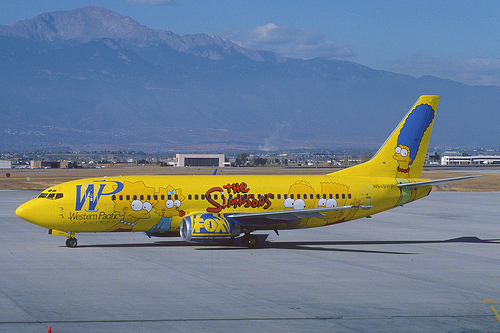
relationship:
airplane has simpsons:
[14, 92, 476, 247] [113, 103, 433, 233]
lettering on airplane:
[204, 182, 273, 213] [14, 92, 476, 247]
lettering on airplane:
[73, 176, 121, 211] [14, 92, 476, 247]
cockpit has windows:
[35, 190, 64, 210] [38, 190, 63, 200]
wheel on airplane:
[65, 234, 77, 245] [14, 96, 476, 246]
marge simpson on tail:
[391, 104, 435, 206] [382, 94, 477, 212]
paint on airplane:
[395, 105, 435, 160] [14, 92, 476, 247]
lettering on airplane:
[208, 179, 276, 212] [14, 92, 476, 247]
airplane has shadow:
[14, 92, 476, 247] [203, 246, 498, 256]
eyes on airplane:
[163, 197, 183, 208] [14, 92, 476, 247]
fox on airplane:
[193, 215, 227, 233] [14, 92, 476, 247]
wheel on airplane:
[66, 237, 77, 246] [14, 92, 476, 247]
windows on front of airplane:
[37, 190, 65, 200] [14, 92, 476, 247]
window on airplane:
[108, 192, 118, 203] [14, 92, 476, 247]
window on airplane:
[111, 195, 117, 201] [14, 92, 476, 247]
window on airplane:
[126, 192, 132, 204] [14, 92, 476, 247]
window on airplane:
[146, 194, 151, 200] [14, 92, 476, 247]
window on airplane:
[146, 192, 153, 202] [14, 92, 476, 247]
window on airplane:
[160, 194, 165, 200] [14, 92, 476, 247]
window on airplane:
[158, 191, 167, 203] [14, 92, 476, 247]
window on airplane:
[186, 191, 194, 202] [14, 92, 476, 247]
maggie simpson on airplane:
[147, 181, 187, 234] [14, 92, 476, 247]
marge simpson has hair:
[391, 104, 435, 206] [396, 102, 436, 163]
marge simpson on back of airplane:
[391, 104, 435, 206] [14, 92, 476, 247]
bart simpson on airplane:
[318, 181, 362, 225] [14, 92, 476, 247]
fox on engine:
[193, 215, 227, 233] [177, 211, 237, 243]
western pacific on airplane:
[67, 209, 123, 220] [14, 92, 476, 247]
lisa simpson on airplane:
[104, 179, 157, 232] [14, 92, 476, 247]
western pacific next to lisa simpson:
[67, 209, 123, 220] [104, 179, 157, 232]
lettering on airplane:
[73, 179, 125, 210] [14, 92, 476, 247]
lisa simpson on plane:
[104, 181, 159, 232] [7, 78, 457, 291]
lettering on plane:
[204, 182, 273, 213] [9, 91, 469, 271]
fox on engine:
[185, 211, 235, 246] [177, 204, 238, 270]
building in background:
[174, 154, 231, 167] [5, 37, 484, 315]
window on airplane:
[111, 195, 117, 201] [2, 139, 472, 268]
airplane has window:
[12, 86, 444, 255] [104, 190, 118, 202]